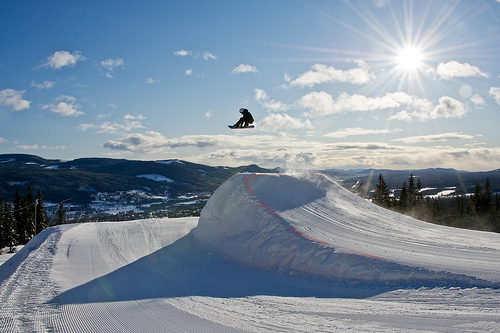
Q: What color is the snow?
A: White.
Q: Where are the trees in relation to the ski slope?
A: On the side.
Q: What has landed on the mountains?
A: Snow.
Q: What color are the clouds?
A: White.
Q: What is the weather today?
A: Sunny.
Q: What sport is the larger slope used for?
A: Snowboarding.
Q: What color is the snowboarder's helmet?
A: White.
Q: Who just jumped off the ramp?
A: Snowboarder.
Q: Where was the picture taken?
A: On a ski slope.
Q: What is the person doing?
A: Snowboarding.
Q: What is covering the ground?
A: Snow.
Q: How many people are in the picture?
A: 1.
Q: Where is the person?
A: In the air.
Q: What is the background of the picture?
A: Mountains.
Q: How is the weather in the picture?
A: Sunny.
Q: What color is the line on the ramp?
A: Orange.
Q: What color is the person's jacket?
A: Black.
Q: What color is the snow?
A: White.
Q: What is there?
A: Mountains.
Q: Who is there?
A: Snowboarder.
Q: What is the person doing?
A: Snowboarding.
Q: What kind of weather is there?
A: It is clear.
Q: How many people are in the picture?
A: One.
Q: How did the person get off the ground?
A: Using the ramp.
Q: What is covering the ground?
A: Snow.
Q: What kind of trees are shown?
A: Pine.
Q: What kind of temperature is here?
A: Cold.